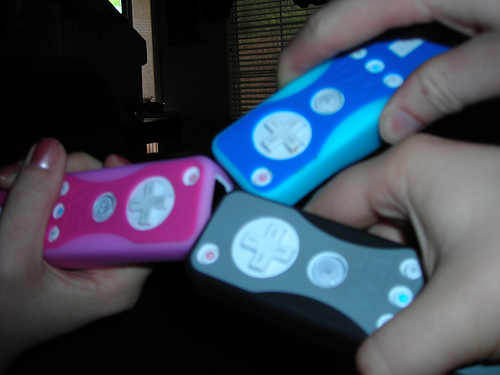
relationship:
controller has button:
[45, 162, 235, 264] [185, 164, 202, 184]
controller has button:
[45, 162, 235, 264] [56, 178, 72, 193]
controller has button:
[45, 162, 235, 264] [51, 204, 66, 219]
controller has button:
[45, 162, 235, 264] [49, 226, 63, 241]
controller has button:
[190, 188, 430, 342] [198, 243, 219, 263]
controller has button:
[190, 188, 430, 342] [237, 222, 298, 275]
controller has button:
[190, 188, 430, 342] [405, 258, 424, 280]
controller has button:
[190, 188, 430, 342] [391, 289, 413, 308]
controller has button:
[203, 28, 449, 206] [351, 46, 367, 61]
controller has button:
[203, 28, 449, 206] [367, 58, 382, 75]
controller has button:
[203, 28, 449, 206] [384, 72, 403, 90]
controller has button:
[203, 28, 449, 206] [312, 88, 350, 113]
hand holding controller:
[1, 138, 151, 368] [45, 162, 235, 264]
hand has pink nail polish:
[1, 138, 151, 368] [31, 139, 62, 172]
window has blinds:
[214, 2, 329, 144] [230, 2, 311, 123]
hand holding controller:
[276, 2, 499, 146] [203, 28, 449, 206]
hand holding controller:
[295, 135, 499, 374] [190, 188, 430, 342]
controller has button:
[45, 162, 235, 264] [129, 178, 175, 225]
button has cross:
[129, 178, 175, 225] [132, 182, 169, 223]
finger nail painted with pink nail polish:
[29, 137, 65, 169] [31, 139, 62, 172]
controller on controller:
[190, 188, 430, 342] [190, 188, 430, 342]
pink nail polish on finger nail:
[31, 139, 62, 172] [29, 137, 65, 169]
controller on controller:
[45, 162, 235, 264] [45, 162, 235, 264]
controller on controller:
[203, 28, 449, 206] [203, 28, 449, 206]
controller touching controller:
[45, 162, 235, 264] [190, 188, 430, 342]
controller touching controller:
[203, 28, 449, 206] [45, 162, 235, 264]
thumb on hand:
[3, 137, 67, 277] [1, 138, 151, 368]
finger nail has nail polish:
[115, 154, 131, 167] [114, 156, 131, 169]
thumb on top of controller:
[3, 137, 67, 277] [45, 162, 235, 264]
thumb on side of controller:
[3, 137, 67, 277] [45, 162, 235, 264]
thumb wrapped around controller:
[3, 137, 67, 277] [45, 162, 235, 264]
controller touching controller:
[45, 162, 235, 264] [203, 28, 449, 206]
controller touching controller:
[190, 188, 430, 342] [203, 28, 449, 206]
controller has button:
[190, 188, 430, 342] [376, 311, 395, 330]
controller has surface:
[190, 188, 430, 342] [190, 187, 422, 332]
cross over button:
[132, 182, 169, 223] [129, 178, 175, 225]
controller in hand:
[45, 162, 235, 264] [1, 138, 151, 368]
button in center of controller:
[129, 178, 175, 225] [45, 162, 235, 264]